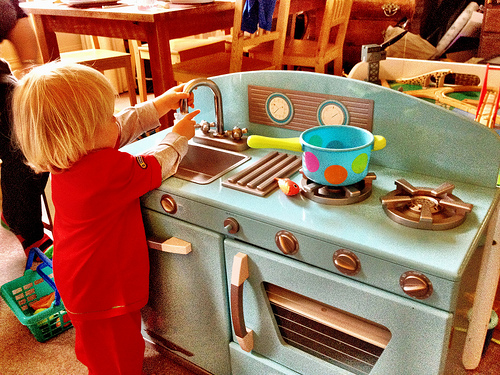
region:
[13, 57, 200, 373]
blond toddler in red pants and red top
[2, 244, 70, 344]
green plastic basket with blue handle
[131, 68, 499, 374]
light blue toy stove with silver knobs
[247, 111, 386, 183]
blue toy pot with yellow handle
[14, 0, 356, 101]
light brown wood table and chairs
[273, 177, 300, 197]
orange and yellow plastic goldfish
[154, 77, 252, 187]
toy sink with silver knobs and spout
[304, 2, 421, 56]
light brown wood bureau with gold handles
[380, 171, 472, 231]
silver burner on toy stove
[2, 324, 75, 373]
beige pile carpet on floor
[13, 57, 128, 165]
Head of blonde child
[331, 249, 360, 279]
Knob on toy stove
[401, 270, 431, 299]
Knob on toy stove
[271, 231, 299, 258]
Knob on toy stove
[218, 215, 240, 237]
oven knob on toy stove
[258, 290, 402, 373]
Oven view on toy stove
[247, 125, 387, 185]
Saucepan on toy stove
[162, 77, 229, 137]
Child's hands on toy faucet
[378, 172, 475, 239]
Burner on toy stove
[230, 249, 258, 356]
Oven handle on toy stove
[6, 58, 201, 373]
blonde toddler playing with sink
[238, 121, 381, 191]
red yellow orange and pink pot on stove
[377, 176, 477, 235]
gas burner on stove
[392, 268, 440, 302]
controls for stove top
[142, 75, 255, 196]
child sized kitchen sink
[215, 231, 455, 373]
child sized oven door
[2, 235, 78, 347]
green plastic shopping basket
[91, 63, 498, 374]
child's kitchen play set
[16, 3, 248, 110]
brown wooden dinner table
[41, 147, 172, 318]
child's red casual shirt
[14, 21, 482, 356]
a kid playing at a kitchen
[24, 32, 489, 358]
a kid playing on a kid kitchen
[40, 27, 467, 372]
a kid play kitchen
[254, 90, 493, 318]
a pot on a fake stove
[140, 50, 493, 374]
a blue play kitchen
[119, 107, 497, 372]
a play kitchen with an oven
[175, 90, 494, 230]
fake pot ona fake stove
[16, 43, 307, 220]
a kid playing at a sink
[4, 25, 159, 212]
a kid with blonde hair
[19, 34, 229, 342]
a young kid with blonde hair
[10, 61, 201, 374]
Little boy washing his hands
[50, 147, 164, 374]
Red outfit worn by little boy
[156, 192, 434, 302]
Knobs on play stove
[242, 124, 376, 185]
Aqua colored pot with yellow handle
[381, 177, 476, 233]
Chrome colored eye of stove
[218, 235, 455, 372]
Stove door on right side of stove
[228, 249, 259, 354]
Brown and beige door handle of stove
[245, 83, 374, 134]
Decoration on back panel of stove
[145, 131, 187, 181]
Beige under shirt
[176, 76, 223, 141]
Faucet attached to the sink